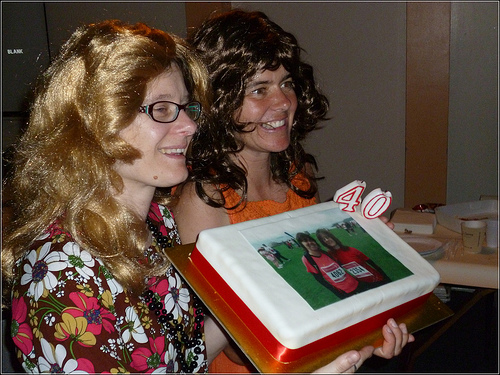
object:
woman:
[0, 18, 376, 373]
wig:
[0, 18, 216, 299]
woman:
[179, 6, 419, 374]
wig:
[185, 4, 337, 217]